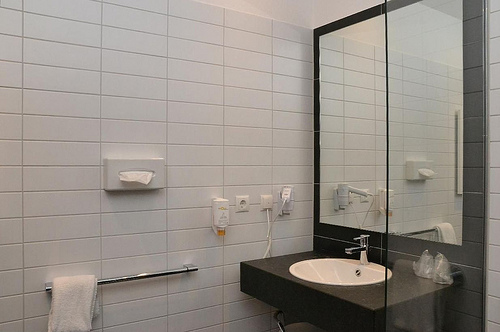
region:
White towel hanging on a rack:
[47, 274, 98, 330]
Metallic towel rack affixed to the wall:
[44, 263, 199, 292]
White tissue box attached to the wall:
[103, 158, 165, 190]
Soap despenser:
[210, 197, 230, 237]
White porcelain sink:
[288, 257, 393, 287]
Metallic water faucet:
[343, 232, 370, 266]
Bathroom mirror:
[317, 1, 462, 246]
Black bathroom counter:
[239, 249, 458, 329]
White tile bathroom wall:
[0, 1, 314, 330]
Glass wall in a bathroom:
[383, 0, 485, 331]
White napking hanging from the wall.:
[118, 161, 153, 185]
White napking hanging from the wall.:
[73, 108, 75, 170]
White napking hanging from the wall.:
[342, 152, 367, 227]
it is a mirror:
[320, 1, 465, 243]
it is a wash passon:
[287, 256, 398, 289]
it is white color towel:
[47, 268, 107, 330]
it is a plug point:
[253, 175, 302, 217]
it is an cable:
[261, 211, 276, 255]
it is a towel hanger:
[43, 263, 221, 299]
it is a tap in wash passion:
[344, 226, 381, 268]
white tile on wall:
[21, 12, 103, 46]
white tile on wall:
[23, 35, 102, 67]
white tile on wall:
[21, 60, 102, 95]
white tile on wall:
[22, 88, 102, 118]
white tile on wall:
[24, 114, 101, 142]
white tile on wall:
[20, 139, 102, 164]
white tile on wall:
[21, 164, 101, 190]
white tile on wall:
[21, 190, 101, 214]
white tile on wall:
[100, 70, 170, 98]